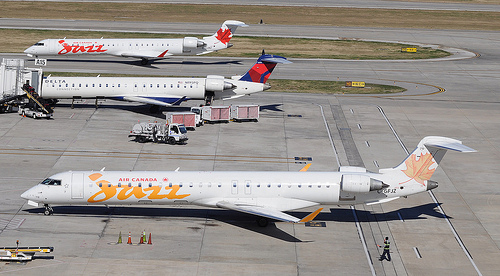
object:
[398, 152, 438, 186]
leaf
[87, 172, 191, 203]
logo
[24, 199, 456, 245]
shadow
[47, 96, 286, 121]
shadow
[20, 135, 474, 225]
aeroplane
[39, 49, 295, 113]
aeroplane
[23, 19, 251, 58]
aeroplane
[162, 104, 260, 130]
carrier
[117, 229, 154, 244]
cones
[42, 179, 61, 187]
glass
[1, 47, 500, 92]
runway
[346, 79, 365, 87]
sign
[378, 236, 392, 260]
man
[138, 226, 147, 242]
man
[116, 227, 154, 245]
neon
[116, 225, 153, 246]
orange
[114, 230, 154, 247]
yellow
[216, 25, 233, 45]
leaf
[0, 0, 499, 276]
floor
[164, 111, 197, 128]
container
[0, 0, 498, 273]
airport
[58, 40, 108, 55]
logo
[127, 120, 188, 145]
truck